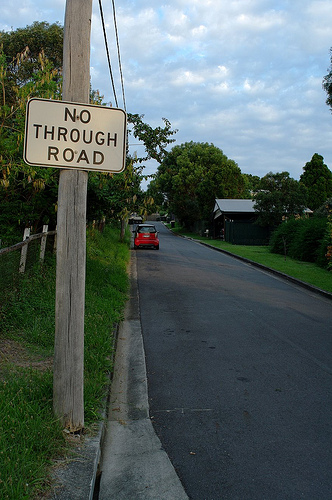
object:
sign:
[22, 97, 127, 173]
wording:
[32, 107, 117, 164]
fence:
[0, 225, 57, 277]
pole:
[52, 0, 93, 434]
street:
[132, 222, 332, 498]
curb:
[99, 252, 151, 499]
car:
[132, 224, 160, 250]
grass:
[0, 223, 128, 498]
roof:
[215, 196, 313, 213]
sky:
[0, 0, 331, 190]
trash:
[171, 221, 176, 228]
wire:
[97, 0, 127, 108]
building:
[213, 197, 314, 246]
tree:
[153, 140, 248, 235]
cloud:
[158, 55, 230, 101]